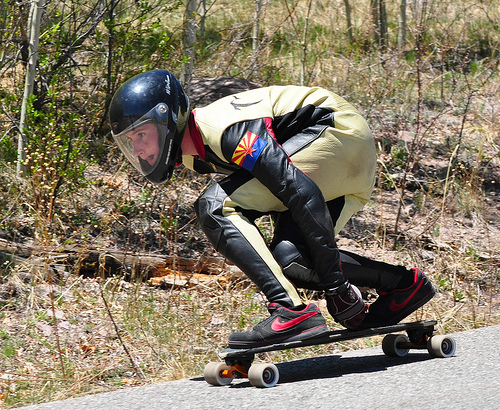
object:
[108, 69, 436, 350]
skateboarder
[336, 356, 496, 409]
road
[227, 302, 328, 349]
shoe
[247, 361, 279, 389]
wheel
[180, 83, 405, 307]
suit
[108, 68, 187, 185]
helmet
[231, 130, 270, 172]
patch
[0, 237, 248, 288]
log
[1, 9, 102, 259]
woods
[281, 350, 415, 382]
shadow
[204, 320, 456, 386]
skateboard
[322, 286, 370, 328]
glove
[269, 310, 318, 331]
logo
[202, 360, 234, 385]
wheel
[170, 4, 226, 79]
tree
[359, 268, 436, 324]
shoe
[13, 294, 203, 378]
foilage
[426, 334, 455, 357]
wheel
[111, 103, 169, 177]
shield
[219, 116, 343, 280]
arm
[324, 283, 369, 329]
hand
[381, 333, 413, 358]
wheel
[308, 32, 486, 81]
hill